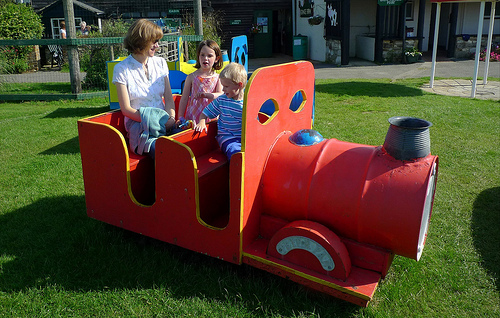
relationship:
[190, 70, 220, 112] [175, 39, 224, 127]
dress on children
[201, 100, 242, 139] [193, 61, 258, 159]
shirt on boy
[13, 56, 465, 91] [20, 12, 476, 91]
road in background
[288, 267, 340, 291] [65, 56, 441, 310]
color on side of train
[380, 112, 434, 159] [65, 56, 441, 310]
spout on front of train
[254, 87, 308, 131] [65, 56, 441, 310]
design on train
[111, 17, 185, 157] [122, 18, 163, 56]
people with hair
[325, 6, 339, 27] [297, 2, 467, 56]
animal on wall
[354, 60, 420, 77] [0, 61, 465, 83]
color on road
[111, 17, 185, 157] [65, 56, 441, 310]
people sitting in train train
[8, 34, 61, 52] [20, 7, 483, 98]
post in background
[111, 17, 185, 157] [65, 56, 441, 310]
people sitting in train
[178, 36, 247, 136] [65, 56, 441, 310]
children sitting in train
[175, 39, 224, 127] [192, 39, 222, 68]
children with hair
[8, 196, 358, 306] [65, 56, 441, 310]
shadow cast by train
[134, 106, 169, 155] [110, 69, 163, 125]
sweater draped over arm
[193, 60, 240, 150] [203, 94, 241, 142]
boy in shirt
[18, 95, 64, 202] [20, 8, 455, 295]
grass in park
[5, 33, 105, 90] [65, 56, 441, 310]
fence behind train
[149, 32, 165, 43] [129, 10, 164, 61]
glasses on face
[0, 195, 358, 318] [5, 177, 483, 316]
shadow on ground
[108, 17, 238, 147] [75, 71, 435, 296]
people are in train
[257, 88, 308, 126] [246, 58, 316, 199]
design on wood